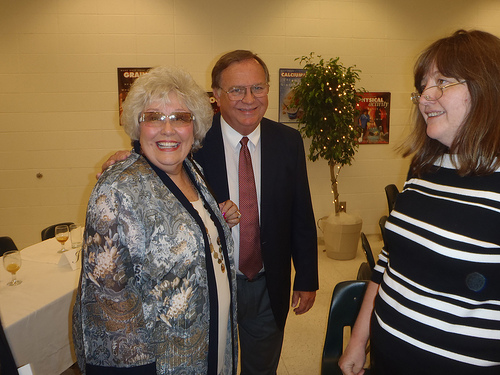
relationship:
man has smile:
[94, 49, 318, 374] [234, 105, 259, 112]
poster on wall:
[276, 67, 312, 126] [0, 3, 494, 233]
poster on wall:
[352, 87, 392, 146] [25, 26, 87, 82]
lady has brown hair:
[338, 30, 500, 375] [397, 29, 496, 178]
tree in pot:
[287, 55, 374, 213] [318, 213, 362, 261]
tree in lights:
[287, 55, 374, 213] [307, 63, 364, 211]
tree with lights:
[287, 55, 374, 213] [307, 63, 364, 211]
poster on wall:
[352, 87, 392, 146] [0, 3, 494, 233]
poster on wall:
[116, 65, 156, 130] [0, 3, 494, 233]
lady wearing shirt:
[68, 59, 245, 373] [361, 140, 498, 372]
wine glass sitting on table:
[56, 224, 69, 254] [0, 224, 84, 374]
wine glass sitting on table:
[2, 248, 22, 287] [0, 224, 84, 374]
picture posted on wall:
[276, 67, 307, 124] [0, 3, 494, 233]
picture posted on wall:
[351, 90, 388, 143] [0, 3, 494, 233]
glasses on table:
[0, 221, 91, 291] [0, 224, 84, 374]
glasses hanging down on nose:
[408, 76, 464, 104] [417, 79, 437, 104]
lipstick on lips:
[154, 137, 179, 151] [148, 136, 190, 156]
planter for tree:
[317, 213, 362, 263] [281, 49, 372, 214]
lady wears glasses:
[68, 59, 245, 373] [138, 110, 193, 130]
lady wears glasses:
[338, 30, 500, 375] [410, 78, 467, 103]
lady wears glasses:
[400, 53, 498, 168] [408, 83, 450, 108]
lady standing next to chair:
[338, 30, 500, 375] [321, 279, 375, 373]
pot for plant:
[319, 214, 364, 263] [291, 53, 364, 216]